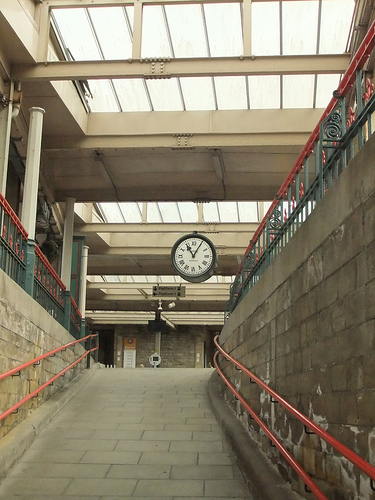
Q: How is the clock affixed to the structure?
A: Mounted on a beam.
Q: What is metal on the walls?
A: Red handrails.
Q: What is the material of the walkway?
A: Bricks.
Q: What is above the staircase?
A: Clock.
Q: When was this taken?
A: 11:05.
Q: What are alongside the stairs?
A: Red rails.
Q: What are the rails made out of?
A: Metal.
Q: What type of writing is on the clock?
A: Roman numerals.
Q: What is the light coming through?
A: Skylights.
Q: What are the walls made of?
A: Stone bricks.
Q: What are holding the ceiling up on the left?
A: Pillars.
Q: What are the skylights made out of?
A: Glass.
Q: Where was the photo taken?
A: In a station.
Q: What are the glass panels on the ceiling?
A: Skylights.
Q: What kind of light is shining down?
A: Sunlight.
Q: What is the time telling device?
A: A clock.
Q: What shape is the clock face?
A: Round.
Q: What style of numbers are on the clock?
A: Roman.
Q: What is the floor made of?
A: Bricks.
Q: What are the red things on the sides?
A: Railings.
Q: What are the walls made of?
A: Bricks.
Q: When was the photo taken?
A: 11:05.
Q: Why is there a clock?
A: To tell the time.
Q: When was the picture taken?
A: In the daytime.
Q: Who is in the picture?
A: No one.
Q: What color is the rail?
A: Red.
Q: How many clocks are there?
A: One.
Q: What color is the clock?
A: Black and White.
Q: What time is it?
A: 11:05.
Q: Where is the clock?
A: Hanging up.